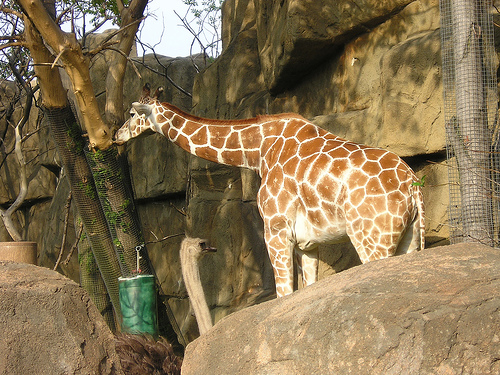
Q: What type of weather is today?
A: It is clear.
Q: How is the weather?
A: It is clear.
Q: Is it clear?
A: Yes, it is clear.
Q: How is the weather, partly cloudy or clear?
A: It is clear.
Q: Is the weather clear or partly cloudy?
A: It is clear.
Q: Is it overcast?
A: No, it is clear.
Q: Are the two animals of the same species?
A: No, they are giraffes and ostriches.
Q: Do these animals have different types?
A: Yes, they are giraffes and ostriches.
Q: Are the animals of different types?
A: Yes, they are giraffes and ostriches.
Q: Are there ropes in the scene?
A: No, there are no ropes.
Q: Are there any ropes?
A: No, there are no ropes.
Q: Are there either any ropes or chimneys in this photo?
A: No, there are no ropes or chimneys.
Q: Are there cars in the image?
A: No, there are no cars.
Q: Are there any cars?
A: No, there are no cars.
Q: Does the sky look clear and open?
A: Yes, the sky is clear and open.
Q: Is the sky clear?
A: Yes, the sky is clear.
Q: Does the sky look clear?
A: Yes, the sky is clear.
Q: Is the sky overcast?
A: No, the sky is clear.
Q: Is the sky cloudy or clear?
A: The sky is clear.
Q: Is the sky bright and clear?
A: Yes, the sky is bright and clear.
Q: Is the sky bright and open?
A: Yes, the sky is bright and open.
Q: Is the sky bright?
A: Yes, the sky is bright.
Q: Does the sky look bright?
A: Yes, the sky is bright.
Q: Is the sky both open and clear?
A: Yes, the sky is open and clear.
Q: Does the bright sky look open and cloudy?
A: No, the sky is open but clear.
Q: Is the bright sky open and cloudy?
A: No, the sky is open but clear.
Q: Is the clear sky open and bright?
A: Yes, the sky is open and bright.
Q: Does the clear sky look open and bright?
A: Yes, the sky is open and bright.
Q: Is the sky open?
A: Yes, the sky is open.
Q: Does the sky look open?
A: Yes, the sky is open.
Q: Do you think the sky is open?
A: Yes, the sky is open.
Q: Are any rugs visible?
A: No, there are no rugs.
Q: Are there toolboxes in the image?
A: No, there are no toolboxes.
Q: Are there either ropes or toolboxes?
A: No, there are no toolboxes or ropes.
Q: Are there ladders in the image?
A: No, there are no ladders.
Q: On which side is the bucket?
A: The bucket is on the left of the image.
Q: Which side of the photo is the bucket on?
A: The bucket is on the left of the image.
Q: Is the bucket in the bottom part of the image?
A: Yes, the bucket is in the bottom of the image.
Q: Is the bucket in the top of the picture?
A: No, the bucket is in the bottom of the image.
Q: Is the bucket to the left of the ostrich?
A: Yes, the bucket is to the left of the ostrich.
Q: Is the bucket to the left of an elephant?
A: No, the bucket is to the left of the ostrich.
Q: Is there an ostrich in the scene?
A: Yes, there is an ostrich.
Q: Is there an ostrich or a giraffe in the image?
A: Yes, there is an ostrich.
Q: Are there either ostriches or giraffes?
A: Yes, there is an ostrich.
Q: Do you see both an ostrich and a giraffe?
A: Yes, there are both an ostrich and a giraffe.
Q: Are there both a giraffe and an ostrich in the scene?
A: Yes, there are both an ostrich and a giraffe.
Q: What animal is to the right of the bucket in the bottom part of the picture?
A: The animal is an ostrich.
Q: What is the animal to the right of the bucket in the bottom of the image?
A: The animal is an ostrich.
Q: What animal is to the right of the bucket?
A: The animal is an ostrich.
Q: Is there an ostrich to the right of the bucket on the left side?
A: Yes, there is an ostrich to the right of the bucket.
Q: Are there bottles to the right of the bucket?
A: No, there is an ostrich to the right of the bucket.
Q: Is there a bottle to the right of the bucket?
A: No, there is an ostrich to the right of the bucket.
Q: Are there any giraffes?
A: Yes, there is a giraffe.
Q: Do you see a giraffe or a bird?
A: Yes, there is a giraffe.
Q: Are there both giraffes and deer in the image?
A: No, there is a giraffe but no deer.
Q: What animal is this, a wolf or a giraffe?
A: This is a giraffe.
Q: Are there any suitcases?
A: No, there are no suitcases.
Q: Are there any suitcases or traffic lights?
A: No, there are no suitcases or traffic lights.